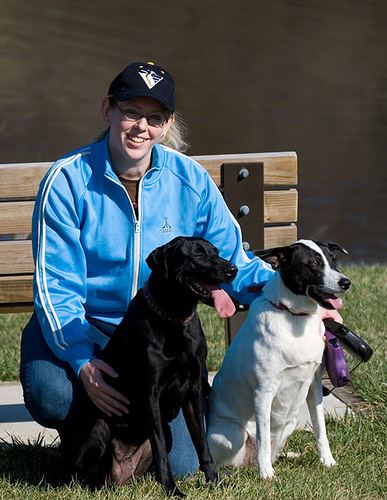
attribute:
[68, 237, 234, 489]
dog — black, sitting, white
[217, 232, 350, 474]
dog — white, looking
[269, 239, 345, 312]
head — black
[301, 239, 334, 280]
streak — white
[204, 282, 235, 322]
tongue — pink, out, hanging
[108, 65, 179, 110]
hat — blue, black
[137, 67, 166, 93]
logo — white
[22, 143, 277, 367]
jacket — blue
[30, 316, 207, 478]
jeans — blue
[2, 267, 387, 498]
grass — green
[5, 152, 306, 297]
bench — wooden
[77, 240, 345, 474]
dogs — black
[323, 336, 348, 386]
leash — purple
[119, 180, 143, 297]
zipper — white